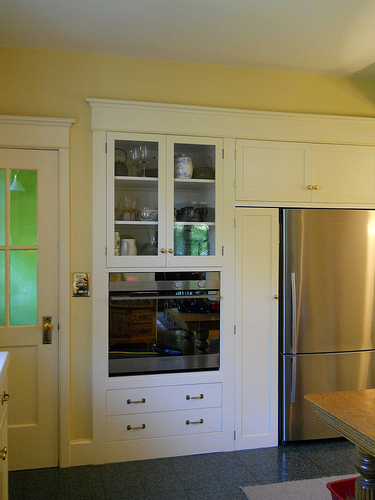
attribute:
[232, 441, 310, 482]
tile — black , Square 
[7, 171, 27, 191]
light fixture — white, gold 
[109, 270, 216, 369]
oven — black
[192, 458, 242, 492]
tile — gray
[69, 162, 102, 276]
wall — white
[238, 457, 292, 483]
tile — gray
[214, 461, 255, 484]
tile — gray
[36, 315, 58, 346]
knob — golden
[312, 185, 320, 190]
knob — golden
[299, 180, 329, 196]
handle — golden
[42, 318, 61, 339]
knob — gold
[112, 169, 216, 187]
shelf — white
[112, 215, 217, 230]
shelf — white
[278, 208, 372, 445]
fridge — silver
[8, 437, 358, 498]
tile — gray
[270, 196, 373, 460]
refrigerator — metal , Silver 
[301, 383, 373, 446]
kitchen counter — brown, granite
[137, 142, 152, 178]
wine glass — empty, clear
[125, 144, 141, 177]
wine glass — empty, clear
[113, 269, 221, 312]
oven — Silver , Black 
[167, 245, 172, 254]
handle — golden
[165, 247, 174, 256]
handle — golden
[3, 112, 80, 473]
door — white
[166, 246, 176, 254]
knob — golden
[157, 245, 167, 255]
knob — golden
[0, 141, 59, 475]
door — white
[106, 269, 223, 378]
oven — black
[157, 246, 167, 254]
knob — golden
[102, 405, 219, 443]
drawer — white, rectangular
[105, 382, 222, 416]
drawer — white, rectangular